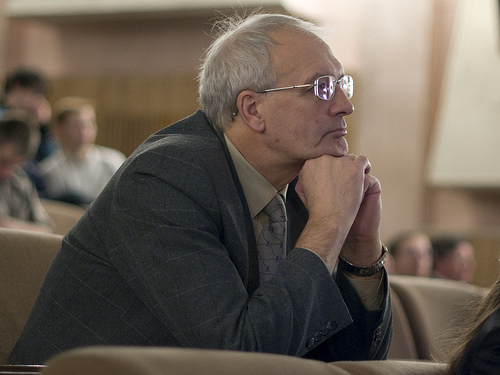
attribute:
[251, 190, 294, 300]
tie — gray 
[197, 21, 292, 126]
hair — gray , short 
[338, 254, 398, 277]
wristband — metal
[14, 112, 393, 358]
suitcoat — gray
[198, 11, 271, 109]
hair — grey, short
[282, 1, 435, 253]
wall — Light 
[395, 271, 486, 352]
seat cushion — brown 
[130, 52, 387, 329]
man — listening 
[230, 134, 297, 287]
dress shirt — tan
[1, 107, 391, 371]
dress jacket — grey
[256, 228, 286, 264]
design — minimal